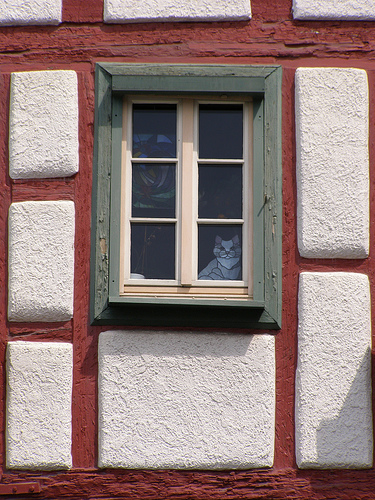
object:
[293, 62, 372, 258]
brick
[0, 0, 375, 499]
wall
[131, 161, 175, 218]
panel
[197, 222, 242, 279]
panel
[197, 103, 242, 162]
glass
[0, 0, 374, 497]
building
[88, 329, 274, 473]
stucco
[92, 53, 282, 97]
frame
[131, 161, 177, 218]
stained glass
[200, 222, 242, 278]
stained glass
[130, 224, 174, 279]
stained glass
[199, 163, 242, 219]
stained glass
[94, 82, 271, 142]
shadow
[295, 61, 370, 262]
block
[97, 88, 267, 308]
frame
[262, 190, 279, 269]
paint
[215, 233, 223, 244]
ear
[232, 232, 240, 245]
ear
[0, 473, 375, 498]
grooves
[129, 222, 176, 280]
potted plant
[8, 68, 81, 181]
square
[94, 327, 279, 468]
square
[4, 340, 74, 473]
square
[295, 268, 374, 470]
square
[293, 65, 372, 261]
square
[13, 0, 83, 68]
wood beam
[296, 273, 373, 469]
block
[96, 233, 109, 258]
paint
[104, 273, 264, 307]
window trim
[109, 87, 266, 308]
paned window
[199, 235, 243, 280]
cat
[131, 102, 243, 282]
panes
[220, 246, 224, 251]
eyes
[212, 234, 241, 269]
head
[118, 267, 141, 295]
corner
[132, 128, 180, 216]
art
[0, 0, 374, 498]
trim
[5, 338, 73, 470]
rectangle